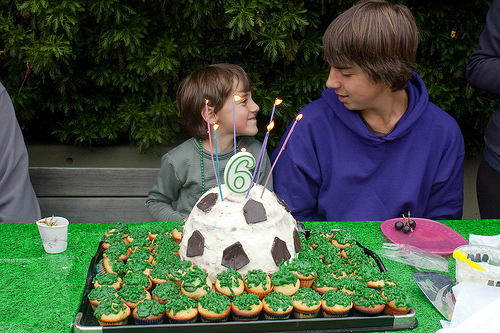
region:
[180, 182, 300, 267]
a half-dome shaped cake resembling a soccer ball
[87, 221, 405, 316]
cupcakes surrounding soccer ball cake have green frosting, thus resembling grass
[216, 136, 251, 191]
number 6 shaped candle on cake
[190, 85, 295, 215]
long thin candles on cake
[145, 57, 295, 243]
young boy sitting behind cake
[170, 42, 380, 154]
boy behind cake grinning at the older boy beside him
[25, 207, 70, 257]
small disposable cup on table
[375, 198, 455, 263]
fruit on pink plate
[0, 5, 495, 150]
tree or shrub behind boys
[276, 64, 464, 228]
older boy wearing blue clothing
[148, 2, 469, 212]
child looking at teenager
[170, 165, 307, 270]
dome shaped cake with white frosting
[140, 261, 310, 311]
vanilla cupcakes with green decoration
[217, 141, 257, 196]
white candle with a number 6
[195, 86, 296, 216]
tall candles on cake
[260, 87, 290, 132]
flames on wick of candle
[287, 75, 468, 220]
purple hoodie sweatshirt on boy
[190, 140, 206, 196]
green necklace on child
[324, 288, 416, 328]
tray containing cupcakes on table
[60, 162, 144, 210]
wood back of bench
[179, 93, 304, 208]
Candles on a birthday cake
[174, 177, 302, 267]
a cake shaped like a soccer ball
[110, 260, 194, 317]
cupcakes with green frosting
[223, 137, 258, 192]
a lit candle shaped like a number 6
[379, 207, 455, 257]
a plate with three grapes on it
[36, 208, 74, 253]
a paper cup with grape stems in it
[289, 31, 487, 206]
a teenager in a blue sweatshirt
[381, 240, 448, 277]
a plastic bag on a table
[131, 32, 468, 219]
two boys looking at each other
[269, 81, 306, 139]
candles that are lit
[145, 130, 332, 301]
soccer ball cake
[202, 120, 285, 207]
six candles on a cake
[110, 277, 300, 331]
green frosting on cupcakes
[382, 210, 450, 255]
pink dish with grapes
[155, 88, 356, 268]
soccer ball cake with cupcakes and candles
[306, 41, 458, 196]
boy in a blue hoodie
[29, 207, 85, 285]
cup with grape stems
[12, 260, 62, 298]
grass colored table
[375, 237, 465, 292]
plastic baggie on table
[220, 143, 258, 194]
Number 6 on cake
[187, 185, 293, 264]
Soccer ball birthday cake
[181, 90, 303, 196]
Six candles on cake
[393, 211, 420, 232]
Fruit on a plate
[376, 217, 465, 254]
Pink lunch plate on table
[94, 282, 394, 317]
Row of green icing cupcakes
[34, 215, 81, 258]
Paper cup on table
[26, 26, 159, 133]
Trees behind birthday boy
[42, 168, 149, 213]
Wooden picnic bench behind table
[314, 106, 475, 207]
Kid with purple hoodie